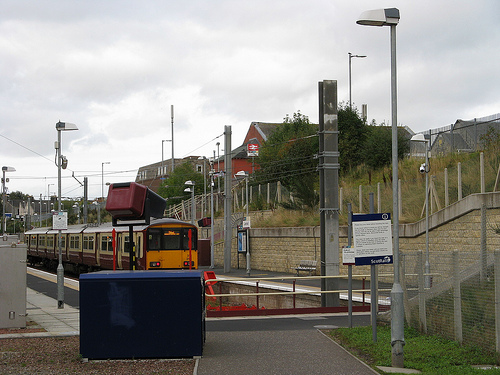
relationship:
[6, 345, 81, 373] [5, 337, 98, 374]
rocks on ground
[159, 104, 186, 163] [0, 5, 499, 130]
pole in sky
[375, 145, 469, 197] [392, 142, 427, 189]
hill full of weeds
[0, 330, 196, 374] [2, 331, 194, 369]
rocks on ground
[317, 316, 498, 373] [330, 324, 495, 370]
patch of grass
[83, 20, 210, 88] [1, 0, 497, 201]
clouds in sky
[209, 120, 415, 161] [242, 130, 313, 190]
roof on building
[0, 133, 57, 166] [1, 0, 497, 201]
power line in sky